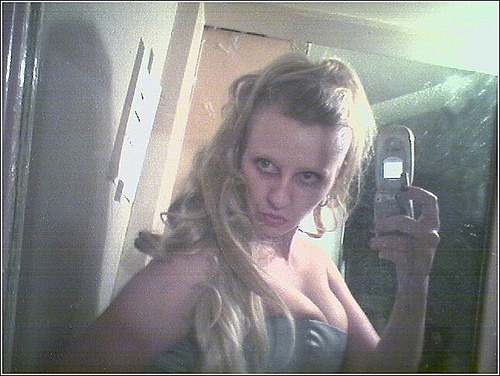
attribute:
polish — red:
[394, 181, 405, 202]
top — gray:
[214, 307, 369, 374]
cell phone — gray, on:
[373, 124, 413, 234]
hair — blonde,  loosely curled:
[135, 49, 377, 373]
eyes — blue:
[253, 155, 322, 185]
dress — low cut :
[147, 316, 350, 374]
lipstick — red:
[259, 210, 286, 226]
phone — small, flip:
[370, 126, 426, 259]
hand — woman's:
[366, 184, 446, 294]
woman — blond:
[144, 63, 390, 361]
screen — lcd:
[382, 155, 400, 181]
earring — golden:
[317, 189, 336, 211]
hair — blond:
[143, 59, 260, 374]